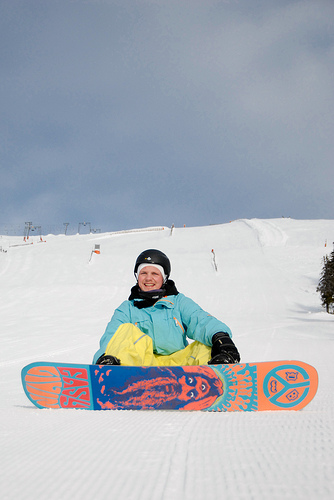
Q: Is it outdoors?
A: Yes, it is outdoors.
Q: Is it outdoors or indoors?
A: It is outdoors.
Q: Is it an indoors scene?
A: No, it is outdoors.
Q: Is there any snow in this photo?
A: Yes, there is snow.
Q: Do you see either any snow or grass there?
A: Yes, there is snow.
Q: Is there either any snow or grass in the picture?
A: Yes, there is snow.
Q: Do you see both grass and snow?
A: No, there is snow but no grass.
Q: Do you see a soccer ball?
A: No, there are no soccer balls.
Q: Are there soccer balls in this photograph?
A: No, there are no soccer balls.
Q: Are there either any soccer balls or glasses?
A: No, there are no soccer balls or glasses.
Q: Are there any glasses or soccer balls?
A: No, there are no soccer balls or glasses.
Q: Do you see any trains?
A: No, there are no trains.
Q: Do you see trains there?
A: No, there are no trains.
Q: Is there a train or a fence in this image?
A: No, there are no trains or fences.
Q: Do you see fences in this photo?
A: No, there are no fences.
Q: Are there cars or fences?
A: No, there are no fences or cars.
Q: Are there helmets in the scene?
A: Yes, there is a helmet.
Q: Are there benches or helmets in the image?
A: Yes, there is a helmet.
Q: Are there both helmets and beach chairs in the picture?
A: No, there is a helmet but no beach chairs.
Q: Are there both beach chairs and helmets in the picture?
A: No, there is a helmet but no beach chairs.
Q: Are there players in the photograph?
A: No, there are no players.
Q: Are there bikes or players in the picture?
A: No, there are no players or bikes.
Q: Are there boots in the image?
A: Yes, there are boots.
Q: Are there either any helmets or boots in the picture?
A: Yes, there are boots.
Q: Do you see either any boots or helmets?
A: Yes, there are boots.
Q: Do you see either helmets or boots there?
A: Yes, there are boots.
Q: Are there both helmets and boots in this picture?
A: Yes, there are both boots and a helmet.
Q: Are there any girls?
A: No, there are no girls.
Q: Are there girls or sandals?
A: No, there are no girls or sandals.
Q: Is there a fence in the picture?
A: No, there are no fences.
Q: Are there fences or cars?
A: No, there are no fences or cars.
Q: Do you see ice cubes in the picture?
A: No, there are no ice cubes.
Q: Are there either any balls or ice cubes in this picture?
A: No, there are no ice cubes or balls.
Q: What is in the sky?
A: The clouds are in the sky.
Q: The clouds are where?
A: The clouds are in the sky.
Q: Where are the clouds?
A: The clouds are in the sky.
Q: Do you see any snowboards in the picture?
A: Yes, there is a snowboard.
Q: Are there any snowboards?
A: Yes, there is a snowboard.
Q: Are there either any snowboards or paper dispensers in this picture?
A: Yes, there is a snowboard.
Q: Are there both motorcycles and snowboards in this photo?
A: No, there is a snowboard but no motorcycles.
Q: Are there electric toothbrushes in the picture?
A: No, there are no electric toothbrushes.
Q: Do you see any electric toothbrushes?
A: No, there are no electric toothbrushes.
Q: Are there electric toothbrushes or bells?
A: No, there are no electric toothbrushes or bells.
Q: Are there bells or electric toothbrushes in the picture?
A: No, there are no electric toothbrushes or bells.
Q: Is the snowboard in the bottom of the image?
A: Yes, the snowboard is in the bottom of the image.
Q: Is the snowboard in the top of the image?
A: No, the snowboard is in the bottom of the image.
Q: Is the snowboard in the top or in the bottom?
A: The snowboard is in the bottom of the image.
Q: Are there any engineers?
A: No, there are no engineers.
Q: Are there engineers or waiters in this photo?
A: No, there are no engineers or waiters.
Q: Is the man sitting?
A: Yes, the man is sitting.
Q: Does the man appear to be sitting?
A: Yes, the man is sitting.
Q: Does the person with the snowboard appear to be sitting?
A: Yes, the man is sitting.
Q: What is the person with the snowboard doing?
A: The man is sitting.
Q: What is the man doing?
A: The man is sitting.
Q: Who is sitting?
A: The man is sitting.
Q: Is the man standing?
A: No, the man is sitting.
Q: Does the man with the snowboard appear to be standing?
A: No, the man is sitting.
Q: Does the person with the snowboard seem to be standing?
A: No, the man is sitting.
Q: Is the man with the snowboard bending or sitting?
A: The man is sitting.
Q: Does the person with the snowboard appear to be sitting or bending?
A: The man is sitting.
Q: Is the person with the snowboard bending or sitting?
A: The man is sitting.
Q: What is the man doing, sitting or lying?
A: The man is sitting.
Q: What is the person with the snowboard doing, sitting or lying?
A: The man is sitting.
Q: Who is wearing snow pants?
A: The man is wearing snow pants.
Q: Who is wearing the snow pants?
A: The man is wearing snow pants.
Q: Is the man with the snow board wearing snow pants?
A: Yes, the man is wearing snow pants.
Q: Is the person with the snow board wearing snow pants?
A: Yes, the man is wearing snow pants.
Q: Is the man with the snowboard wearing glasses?
A: No, the man is wearing snow pants.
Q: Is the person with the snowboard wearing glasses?
A: No, the man is wearing snow pants.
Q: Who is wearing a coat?
A: The man is wearing a coat.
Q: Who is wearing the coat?
A: The man is wearing a coat.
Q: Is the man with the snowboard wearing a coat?
A: Yes, the man is wearing a coat.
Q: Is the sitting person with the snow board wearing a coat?
A: Yes, the man is wearing a coat.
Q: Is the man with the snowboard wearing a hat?
A: No, the man is wearing a coat.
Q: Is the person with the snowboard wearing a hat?
A: No, the man is wearing a coat.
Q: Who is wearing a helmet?
A: The man is wearing a helmet.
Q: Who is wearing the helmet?
A: The man is wearing a helmet.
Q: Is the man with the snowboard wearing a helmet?
A: Yes, the man is wearing a helmet.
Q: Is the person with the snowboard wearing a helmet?
A: Yes, the man is wearing a helmet.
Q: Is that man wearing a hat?
A: No, the man is wearing a helmet.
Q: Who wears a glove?
A: The man wears a glove.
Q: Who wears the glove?
A: The man wears a glove.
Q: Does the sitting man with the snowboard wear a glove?
A: Yes, the man wears a glove.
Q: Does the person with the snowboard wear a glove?
A: Yes, the man wears a glove.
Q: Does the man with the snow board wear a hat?
A: No, the man wears a glove.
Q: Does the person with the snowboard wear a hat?
A: No, the man wears a glove.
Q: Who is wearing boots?
A: The man is wearing boots.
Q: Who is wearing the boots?
A: The man is wearing boots.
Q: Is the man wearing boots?
A: Yes, the man is wearing boots.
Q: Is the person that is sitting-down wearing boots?
A: Yes, the man is wearing boots.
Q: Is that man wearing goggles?
A: No, the man is wearing boots.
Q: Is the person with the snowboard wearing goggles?
A: No, the man is wearing boots.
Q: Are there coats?
A: Yes, there is a coat.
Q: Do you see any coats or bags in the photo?
A: Yes, there is a coat.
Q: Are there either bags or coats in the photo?
A: Yes, there is a coat.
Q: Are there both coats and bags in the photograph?
A: No, there is a coat but no bags.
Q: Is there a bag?
A: No, there are no bags.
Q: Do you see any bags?
A: No, there are no bags.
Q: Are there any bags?
A: No, there are no bags.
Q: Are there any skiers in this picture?
A: No, there are no skiers.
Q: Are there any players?
A: No, there are no players.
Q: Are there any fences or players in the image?
A: No, there are no players or fences.